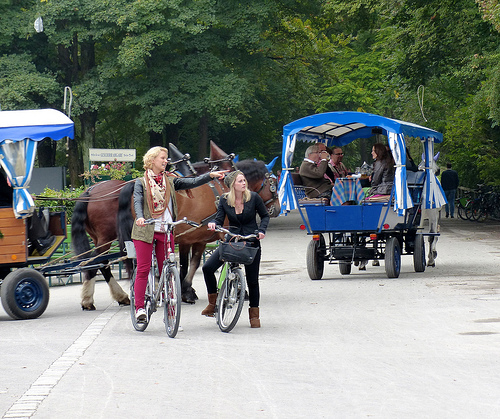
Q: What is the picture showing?
A: It is showing a road.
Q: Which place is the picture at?
A: It is at the road.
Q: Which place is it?
A: It is a road.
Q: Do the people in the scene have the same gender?
A: No, they are both male and female.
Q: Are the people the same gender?
A: No, they are both male and female.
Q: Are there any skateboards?
A: No, there are no skateboards.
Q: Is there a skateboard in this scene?
A: No, there are no skateboards.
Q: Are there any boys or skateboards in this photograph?
A: No, there are no skateboards or boys.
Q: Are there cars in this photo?
A: No, there are no cars.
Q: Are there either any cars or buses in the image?
A: No, there are no cars or buses.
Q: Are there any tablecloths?
A: Yes, there is a tablecloth.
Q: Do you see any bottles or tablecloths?
A: Yes, there is a tablecloth.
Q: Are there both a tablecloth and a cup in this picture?
A: No, there is a tablecloth but no cups.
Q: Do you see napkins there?
A: No, there are no napkins.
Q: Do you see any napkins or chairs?
A: No, there are no napkins or chairs.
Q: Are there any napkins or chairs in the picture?
A: No, there are no napkins or chairs.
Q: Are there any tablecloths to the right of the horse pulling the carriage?
A: Yes, there is a tablecloth to the right of the horse.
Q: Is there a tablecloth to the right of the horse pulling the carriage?
A: Yes, there is a tablecloth to the right of the horse.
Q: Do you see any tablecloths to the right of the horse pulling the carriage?
A: Yes, there is a tablecloth to the right of the horse.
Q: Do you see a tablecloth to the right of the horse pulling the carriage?
A: Yes, there is a tablecloth to the right of the horse.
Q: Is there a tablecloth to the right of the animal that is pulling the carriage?
A: Yes, there is a tablecloth to the right of the horse.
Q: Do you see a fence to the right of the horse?
A: No, there is a tablecloth to the right of the horse.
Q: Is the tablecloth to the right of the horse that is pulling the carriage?
A: Yes, the tablecloth is to the right of the horse.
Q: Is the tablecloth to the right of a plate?
A: No, the tablecloth is to the right of the horse.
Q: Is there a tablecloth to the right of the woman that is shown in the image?
A: Yes, there is a tablecloth to the right of the woman.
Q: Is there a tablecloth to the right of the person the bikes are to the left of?
A: Yes, there is a tablecloth to the right of the woman.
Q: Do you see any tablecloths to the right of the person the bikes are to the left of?
A: Yes, there is a tablecloth to the right of the woman.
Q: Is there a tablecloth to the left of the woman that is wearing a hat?
A: No, the tablecloth is to the right of the woman.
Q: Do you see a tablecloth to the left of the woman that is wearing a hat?
A: No, the tablecloth is to the right of the woman.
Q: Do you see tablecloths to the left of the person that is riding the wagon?
A: No, the tablecloth is to the right of the woman.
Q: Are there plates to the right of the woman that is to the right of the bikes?
A: No, there is a tablecloth to the right of the woman.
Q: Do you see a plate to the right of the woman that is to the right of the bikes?
A: No, there is a tablecloth to the right of the woman.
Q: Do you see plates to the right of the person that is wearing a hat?
A: No, there is a tablecloth to the right of the woman.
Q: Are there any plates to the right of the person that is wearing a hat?
A: No, there is a tablecloth to the right of the woman.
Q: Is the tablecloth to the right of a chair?
A: No, the tablecloth is to the right of a woman.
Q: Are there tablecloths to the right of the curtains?
A: Yes, there is a tablecloth to the right of the curtains.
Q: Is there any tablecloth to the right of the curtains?
A: Yes, there is a tablecloth to the right of the curtains.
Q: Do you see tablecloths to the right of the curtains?
A: Yes, there is a tablecloth to the right of the curtains.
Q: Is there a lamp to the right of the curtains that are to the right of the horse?
A: No, there is a tablecloth to the right of the curtains.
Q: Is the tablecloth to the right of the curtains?
A: Yes, the tablecloth is to the right of the curtains.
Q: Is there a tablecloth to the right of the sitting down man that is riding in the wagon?
A: Yes, there is a tablecloth to the right of the man.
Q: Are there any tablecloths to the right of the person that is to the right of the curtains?
A: Yes, there is a tablecloth to the right of the man.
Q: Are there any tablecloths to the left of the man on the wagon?
A: No, the tablecloth is to the right of the man.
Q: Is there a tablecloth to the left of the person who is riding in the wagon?
A: No, the tablecloth is to the right of the man.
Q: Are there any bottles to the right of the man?
A: No, there is a tablecloth to the right of the man.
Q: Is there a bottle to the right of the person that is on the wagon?
A: No, there is a tablecloth to the right of the man.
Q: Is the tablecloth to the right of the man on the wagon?
A: Yes, the tablecloth is to the right of the man.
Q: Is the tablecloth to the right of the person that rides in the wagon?
A: Yes, the tablecloth is to the right of the man.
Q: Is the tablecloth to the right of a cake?
A: No, the tablecloth is to the right of the man.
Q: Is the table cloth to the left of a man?
A: No, the table cloth is to the right of a man.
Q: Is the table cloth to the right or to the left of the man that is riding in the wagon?
A: The table cloth is to the right of the man.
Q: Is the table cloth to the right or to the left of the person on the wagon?
A: The table cloth is to the right of the man.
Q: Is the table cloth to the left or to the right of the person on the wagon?
A: The table cloth is to the right of the man.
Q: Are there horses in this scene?
A: Yes, there is a horse.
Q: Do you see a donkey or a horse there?
A: Yes, there is a horse.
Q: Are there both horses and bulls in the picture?
A: No, there is a horse but no bulls.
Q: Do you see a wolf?
A: No, there are no wolves.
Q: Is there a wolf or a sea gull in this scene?
A: No, there are no wolves or seagulls.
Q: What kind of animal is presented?
A: The animal is a horse.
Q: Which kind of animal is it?
A: The animal is a horse.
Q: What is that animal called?
A: This is a horse.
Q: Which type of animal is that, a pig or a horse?
A: This is a horse.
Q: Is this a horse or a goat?
A: This is a horse.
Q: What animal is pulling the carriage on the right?
A: The horse is pulling the carriage.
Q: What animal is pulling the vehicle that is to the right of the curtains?
A: The horse is pulling the carriage.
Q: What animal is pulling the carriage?
A: The horse is pulling the carriage.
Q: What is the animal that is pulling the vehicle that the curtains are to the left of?
A: The animal is a horse.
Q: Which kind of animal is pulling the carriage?
A: The animal is a horse.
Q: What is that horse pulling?
A: The horse is pulling the carriage.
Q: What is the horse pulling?
A: The horse is pulling the carriage.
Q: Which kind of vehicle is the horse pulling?
A: The horse is pulling the carriage.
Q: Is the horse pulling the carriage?
A: Yes, the horse is pulling the carriage.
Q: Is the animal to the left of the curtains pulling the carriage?
A: Yes, the horse is pulling the carriage.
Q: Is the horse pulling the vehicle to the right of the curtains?
A: Yes, the horse is pulling the carriage.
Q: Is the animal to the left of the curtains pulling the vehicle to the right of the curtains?
A: Yes, the horse is pulling the carriage.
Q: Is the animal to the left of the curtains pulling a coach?
A: No, the horse is pulling the carriage.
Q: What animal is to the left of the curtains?
A: The animal is a horse.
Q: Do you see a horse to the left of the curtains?
A: Yes, there is a horse to the left of the curtains.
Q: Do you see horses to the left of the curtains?
A: Yes, there is a horse to the left of the curtains.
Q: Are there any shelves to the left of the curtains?
A: No, there is a horse to the left of the curtains.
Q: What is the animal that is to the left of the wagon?
A: The animal is a horse.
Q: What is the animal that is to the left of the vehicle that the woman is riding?
A: The animal is a horse.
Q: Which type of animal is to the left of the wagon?
A: The animal is a horse.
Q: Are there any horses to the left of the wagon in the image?
A: Yes, there is a horse to the left of the wagon.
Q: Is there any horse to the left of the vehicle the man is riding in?
A: Yes, there is a horse to the left of the wagon.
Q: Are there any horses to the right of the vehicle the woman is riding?
A: No, the horse is to the left of the wagon.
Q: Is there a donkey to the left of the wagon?
A: No, there is a horse to the left of the wagon.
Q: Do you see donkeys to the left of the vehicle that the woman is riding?
A: No, there is a horse to the left of the wagon.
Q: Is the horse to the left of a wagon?
A: Yes, the horse is to the left of a wagon.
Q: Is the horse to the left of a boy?
A: No, the horse is to the left of a wagon.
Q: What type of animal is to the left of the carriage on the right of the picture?
A: The animal is a horse.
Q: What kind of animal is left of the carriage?
A: The animal is a horse.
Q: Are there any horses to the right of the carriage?
A: No, the horse is to the left of the carriage.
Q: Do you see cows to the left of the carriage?
A: No, there is a horse to the left of the carriage.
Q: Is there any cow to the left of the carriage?
A: No, there is a horse to the left of the carriage.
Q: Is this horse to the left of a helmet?
A: No, the horse is to the left of the carriage.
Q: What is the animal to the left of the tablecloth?
A: The animal is a horse.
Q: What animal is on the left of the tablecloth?
A: The animal is a horse.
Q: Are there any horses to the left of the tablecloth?
A: Yes, there is a horse to the left of the tablecloth.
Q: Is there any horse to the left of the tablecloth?
A: Yes, there is a horse to the left of the tablecloth.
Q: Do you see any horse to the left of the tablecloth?
A: Yes, there is a horse to the left of the tablecloth.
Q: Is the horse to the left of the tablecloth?
A: Yes, the horse is to the left of the tablecloth.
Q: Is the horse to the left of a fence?
A: No, the horse is to the left of the tablecloth.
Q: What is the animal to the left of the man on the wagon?
A: The animal is a horse.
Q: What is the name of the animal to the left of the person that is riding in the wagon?
A: The animal is a horse.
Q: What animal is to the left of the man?
A: The animal is a horse.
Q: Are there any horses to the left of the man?
A: Yes, there is a horse to the left of the man.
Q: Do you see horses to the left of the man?
A: Yes, there is a horse to the left of the man.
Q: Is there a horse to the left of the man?
A: Yes, there is a horse to the left of the man.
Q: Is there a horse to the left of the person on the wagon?
A: Yes, there is a horse to the left of the man.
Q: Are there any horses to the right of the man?
A: No, the horse is to the left of the man.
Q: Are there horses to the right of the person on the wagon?
A: No, the horse is to the left of the man.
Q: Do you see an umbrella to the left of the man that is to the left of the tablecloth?
A: No, there is a horse to the left of the man.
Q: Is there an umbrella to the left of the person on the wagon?
A: No, there is a horse to the left of the man.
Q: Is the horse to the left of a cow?
A: No, the horse is to the left of a man.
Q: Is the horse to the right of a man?
A: No, the horse is to the left of a man.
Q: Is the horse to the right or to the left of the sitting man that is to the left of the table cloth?
A: The horse is to the left of the man.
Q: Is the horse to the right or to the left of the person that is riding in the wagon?
A: The horse is to the left of the man.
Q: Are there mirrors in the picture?
A: No, there are no mirrors.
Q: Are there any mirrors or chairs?
A: No, there are no mirrors or chairs.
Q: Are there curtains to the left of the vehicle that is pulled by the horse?
A: Yes, there are curtains to the left of the carriage.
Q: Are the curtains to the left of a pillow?
A: No, the curtains are to the left of a carriage.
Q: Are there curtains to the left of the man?
A: Yes, there are curtains to the left of the man.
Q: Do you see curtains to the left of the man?
A: Yes, there are curtains to the left of the man.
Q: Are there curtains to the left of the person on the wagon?
A: Yes, there are curtains to the left of the man.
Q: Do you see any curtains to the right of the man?
A: No, the curtains are to the left of the man.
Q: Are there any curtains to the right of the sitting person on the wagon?
A: No, the curtains are to the left of the man.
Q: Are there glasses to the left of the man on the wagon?
A: No, there are curtains to the left of the man.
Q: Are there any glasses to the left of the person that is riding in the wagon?
A: No, there are curtains to the left of the man.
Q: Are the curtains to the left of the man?
A: Yes, the curtains are to the left of the man.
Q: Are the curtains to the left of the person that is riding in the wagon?
A: Yes, the curtains are to the left of the man.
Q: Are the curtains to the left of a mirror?
A: No, the curtains are to the left of the man.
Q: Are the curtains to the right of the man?
A: No, the curtains are to the left of the man.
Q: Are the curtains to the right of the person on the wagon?
A: No, the curtains are to the left of the man.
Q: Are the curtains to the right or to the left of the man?
A: The curtains are to the left of the man.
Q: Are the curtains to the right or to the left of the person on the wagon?
A: The curtains are to the left of the man.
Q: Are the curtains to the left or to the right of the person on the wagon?
A: The curtains are to the left of the man.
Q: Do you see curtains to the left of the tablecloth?
A: Yes, there are curtains to the left of the tablecloth.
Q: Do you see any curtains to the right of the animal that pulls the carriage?
A: Yes, there are curtains to the right of the horse.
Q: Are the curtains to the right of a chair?
A: No, the curtains are to the right of a horse.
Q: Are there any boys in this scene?
A: No, there are no boys.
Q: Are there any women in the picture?
A: Yes, there is a woman.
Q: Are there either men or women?
A: Yes, there is a woman.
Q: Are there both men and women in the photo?
A: Yes, there are both a woman and a man.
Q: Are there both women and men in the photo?
A: Yes, there are both a woman and a man.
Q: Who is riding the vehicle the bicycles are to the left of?
A: The woman is riding the wagon.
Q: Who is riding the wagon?
A: The woman is riding the wagon.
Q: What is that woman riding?
A: The woman is riding the wagon.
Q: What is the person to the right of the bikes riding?
A: The woman is riding the wagon.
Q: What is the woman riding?
A: The woman is riding the wagon.